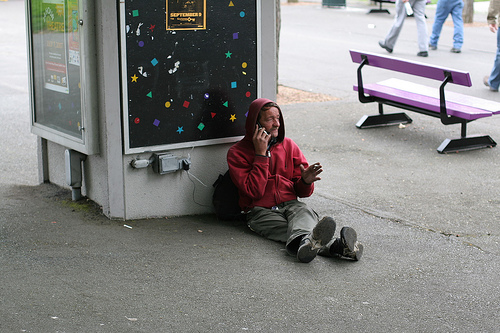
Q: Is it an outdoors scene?
A: Yes, it is outdoors.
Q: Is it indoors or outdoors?
A: It is outdoors.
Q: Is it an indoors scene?
A: No, it is outdoors.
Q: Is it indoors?
A: No, it is outdoors.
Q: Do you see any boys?
A: No, there are no boys.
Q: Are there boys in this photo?
A: No, there are no boys.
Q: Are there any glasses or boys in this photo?
A: No, there are no boys or glasses.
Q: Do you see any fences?
A: No, there are no fences.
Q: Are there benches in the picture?
A: Yes, there is a bench.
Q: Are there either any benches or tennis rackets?
A: Yes, there is a bench.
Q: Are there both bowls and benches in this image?
A: No, there is a bench but no bowls.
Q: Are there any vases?
A: No, there are no vases.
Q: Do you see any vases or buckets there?
A: No, there are no vases or buckets.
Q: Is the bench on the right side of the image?
A: Yes, the bench is on the right of the image.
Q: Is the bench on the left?
A: No, the bench is on the right of the image.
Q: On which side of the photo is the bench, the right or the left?
A: The bench is on the right of the image.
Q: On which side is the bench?
A: The bench is on the right of the image.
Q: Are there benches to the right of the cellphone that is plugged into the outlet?
A: Yes, there is a bench to the right of the cellphone.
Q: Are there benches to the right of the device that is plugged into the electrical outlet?
A: Yes, there is a bench to the right of the cellphone.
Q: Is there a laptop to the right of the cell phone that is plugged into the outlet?
A: No, there is a bench to the right of the mobile phone.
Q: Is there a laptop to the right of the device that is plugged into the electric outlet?
A: No, there is a bench to the right of the mobile phone.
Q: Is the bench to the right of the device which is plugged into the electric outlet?
A: Yes, the bench is to the right of the mobile phone.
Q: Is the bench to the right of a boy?
A: No, the bench is to the right of the mobile phone.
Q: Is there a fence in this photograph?
A: No, there are no fences.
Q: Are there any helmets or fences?
A: No, there are no helmets or fences.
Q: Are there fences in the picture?
A: No, there are no fences.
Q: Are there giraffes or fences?
A: No, there are no fences or giraffes.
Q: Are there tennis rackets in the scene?
A: No, there are no tennis rackets.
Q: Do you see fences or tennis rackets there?
A: No, there are no tennis rackets or fences.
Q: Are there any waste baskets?
A: No, there are no waste baskets.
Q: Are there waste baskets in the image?
A: No, there are no waste baskets.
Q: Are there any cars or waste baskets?
A: No, there are no waste baskets or cars.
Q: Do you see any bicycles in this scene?
A: No, there are no bicycles.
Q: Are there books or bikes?
A: No, there are no bikes or books.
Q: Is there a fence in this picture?
A: No, there are no fences.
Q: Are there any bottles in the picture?
A: Yes, there is a bottle.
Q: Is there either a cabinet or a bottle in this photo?
A: Yes, there is a bottle.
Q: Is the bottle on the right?
A: Yes, the bottle is on the right of the image.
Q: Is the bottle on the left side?
A: No, the bottle is on the right of the image.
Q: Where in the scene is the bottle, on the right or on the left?
A: The bottle is on the right of the image.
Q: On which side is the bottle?
A: The bottle is on the right of the image.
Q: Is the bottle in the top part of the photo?
A: Yes, the bottle is in the top of the image.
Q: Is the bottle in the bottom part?
A: No, the bottle is in the top of the image.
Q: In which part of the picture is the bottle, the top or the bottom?
A: The bottle is in the top of the image.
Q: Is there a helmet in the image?
A: No, there are no helmets.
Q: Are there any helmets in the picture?
A: No, there are no helmets.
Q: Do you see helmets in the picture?
A: No, there are no helmets.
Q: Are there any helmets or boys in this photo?
A: No, there are no helmets or boys.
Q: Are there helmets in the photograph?
A: No, there are no helmets.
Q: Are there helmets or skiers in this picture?
A: No, there are no helmets or skiers.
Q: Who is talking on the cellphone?
A: The man is talking on the cellphone.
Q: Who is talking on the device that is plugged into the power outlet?
A: The man is talking on the cellphone.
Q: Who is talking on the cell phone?
A: The man is talking on the cellphone.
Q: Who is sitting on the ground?
A: The man is sitting on the ground.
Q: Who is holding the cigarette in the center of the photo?
A: The man is holding the cigarette.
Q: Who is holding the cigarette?
A: The man is holding the cigarette.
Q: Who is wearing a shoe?
A: The man is wearing a shoe.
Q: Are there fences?
A: No, there are no fences.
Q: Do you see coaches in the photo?
A: No, there are no coaches.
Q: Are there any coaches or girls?
A: No, there are no coaches or girls.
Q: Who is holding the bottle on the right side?
A: The man is holding the bottle.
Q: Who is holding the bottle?
A: The man is holding the bottle.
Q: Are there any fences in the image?
A: No, there are no fences.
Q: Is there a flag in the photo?
A: No, there are no flags.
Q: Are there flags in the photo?
A: No, there are no flags.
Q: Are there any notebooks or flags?
A: No, there are no flags or notebooks.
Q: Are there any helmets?
A: No, there are no helmets.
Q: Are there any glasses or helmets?
A: No, there are no helmets or glasses.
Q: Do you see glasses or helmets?
A: No, there are no helmets or glasses.